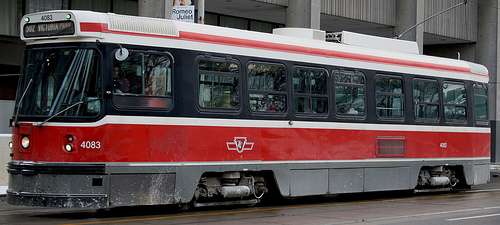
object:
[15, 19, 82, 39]
sign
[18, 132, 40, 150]
headlights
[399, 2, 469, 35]
pole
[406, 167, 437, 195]
ground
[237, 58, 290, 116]
window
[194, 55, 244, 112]
window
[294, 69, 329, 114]
window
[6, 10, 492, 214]
bus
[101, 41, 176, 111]
window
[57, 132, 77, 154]
headlight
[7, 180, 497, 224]
road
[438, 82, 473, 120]
window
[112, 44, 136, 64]
mirror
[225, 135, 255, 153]
design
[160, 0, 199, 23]
sign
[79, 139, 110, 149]
tram number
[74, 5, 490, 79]
roof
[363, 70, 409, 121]
window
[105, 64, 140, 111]
conductor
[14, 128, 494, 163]
background